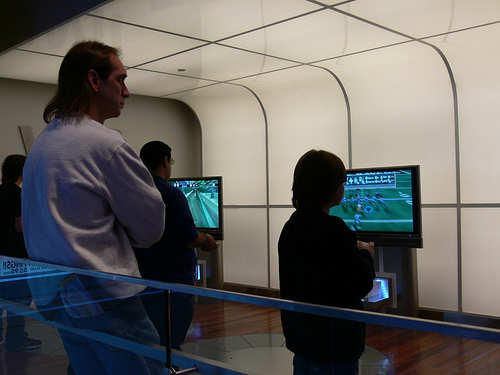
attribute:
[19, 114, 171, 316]
sweatshirt — white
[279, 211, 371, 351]
shirt — black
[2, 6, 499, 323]
wall — white, reflective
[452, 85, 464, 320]
lines — black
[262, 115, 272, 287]
lines — black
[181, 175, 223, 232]
screen — green, game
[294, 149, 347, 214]
hair — black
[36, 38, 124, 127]
hair — black, thinning, shoulder-length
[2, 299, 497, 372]
floor — black, brown, wood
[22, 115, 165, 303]
shirt — grey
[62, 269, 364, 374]
top — clear, glass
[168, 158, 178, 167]
glasses — reading glasses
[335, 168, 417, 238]
screen — green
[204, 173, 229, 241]
frame — black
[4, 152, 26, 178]
hair — black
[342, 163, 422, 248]
frame — black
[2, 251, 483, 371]
railings — silver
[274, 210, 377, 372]
outfit — black